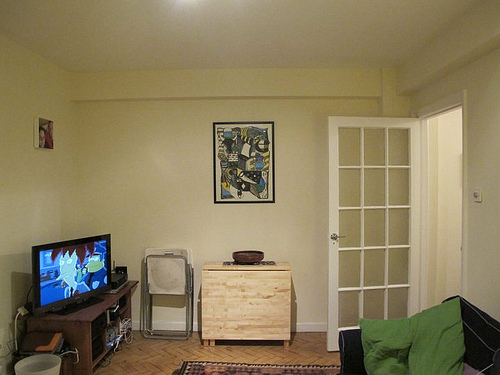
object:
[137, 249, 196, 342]
folded chairs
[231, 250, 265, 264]
bowl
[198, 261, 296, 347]
table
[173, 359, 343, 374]
rug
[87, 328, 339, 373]
floor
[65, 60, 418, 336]
wall